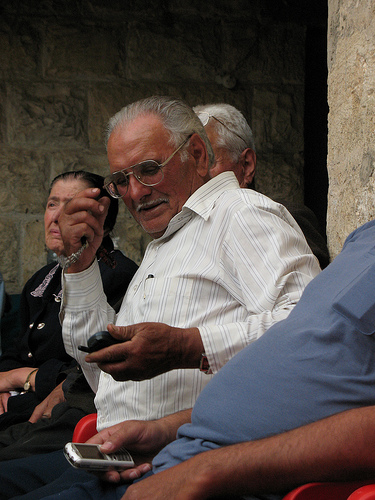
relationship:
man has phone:
[0, 85, 327, 500] [77, 329, 120, 356]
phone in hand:
[77, 329, 120, 356] [83, 319, 185, 383]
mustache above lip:
[136, 199, 166, 212] [139, 201, 166, 217]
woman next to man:
[0, 169, 139, 429] [0, 85, 327, 500]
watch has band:
[30, 365, 40, 394] [27, 369, 38, 382]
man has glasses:
[0, 85, 327, 500] [109, 130, 193, 200]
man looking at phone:
[0, 85, 327, 500] [77, 329, 120, 356]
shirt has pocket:
[59, 169, 323, 432] [140, 276, 192, 337]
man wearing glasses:
[0, 85, 327, 500] [109, 130, 193, 200]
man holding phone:
[0, 85, 327, 500] [77, 329, 120, 356]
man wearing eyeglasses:
[0, 85, 327, 500] [109, 130, 193, 200]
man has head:
[1, 103, 328, 463] [186, 102, 255, 192]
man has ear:
[0, 85, 327, 500] [185, 132, 209, 176]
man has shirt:
[0, 85, 327, 500] [59, 169, 323, 432]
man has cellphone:
[0, 85, 327, 500] [77, 329, 120, 356]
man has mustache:
[0, 85, 327, 500] [136, 199, 166, 212]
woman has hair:
[0, 169, 139, 429] [46, 171, 120, 239]